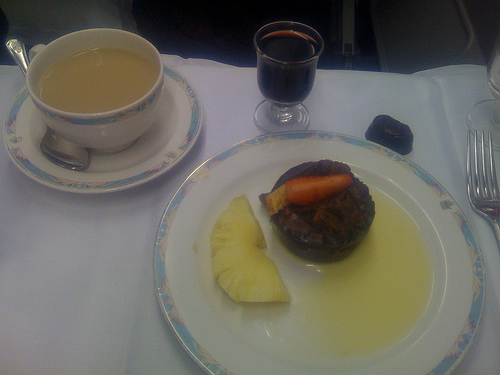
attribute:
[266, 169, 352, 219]
carrot — orange, cooked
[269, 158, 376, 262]
meat — dark brown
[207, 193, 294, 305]
pineapple — sliced, fresh, yellow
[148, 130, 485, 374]
plate — blue, white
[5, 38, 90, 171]
spoon — silver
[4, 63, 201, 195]
saucer — white, blue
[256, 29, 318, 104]
liquid — dark, brown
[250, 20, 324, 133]
glass — full, small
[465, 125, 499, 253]
fork — silver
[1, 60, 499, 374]
tablecloth — white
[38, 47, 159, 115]
gravy — light brown, yellow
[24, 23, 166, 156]
cup — white, blue, bowl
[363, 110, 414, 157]
chocolate — dark, candy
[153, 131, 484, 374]
design — blue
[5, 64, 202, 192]
trim — blue